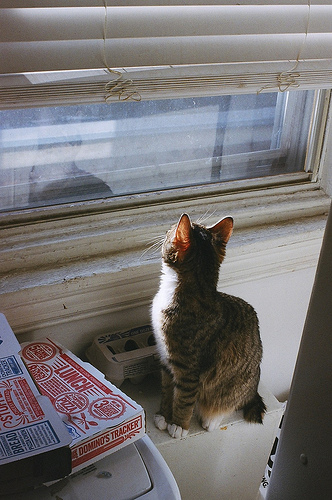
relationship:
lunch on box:
[51, 361, 95, 402] [48, 366, 94, 409]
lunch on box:
[51, 361, 95, 402] [14, 333, 168, 463]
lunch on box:
[51, 361, 95, 402] [22, 334, 158, 486]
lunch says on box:
[51, 361, 95, 402] [22, 334, 158, 486]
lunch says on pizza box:
[51, 361, 95, 402] [36, 341, 133, 441]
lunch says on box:
[51, 361, 95, 402] [23, 334, 158, 476]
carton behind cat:
[85, 320, 158, 388] [149, 213, 267, 438]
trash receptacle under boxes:
[46, 432, 186, 498] [0, 313, 150, 489]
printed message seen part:
[56, 410, 148, 460] [114, 425, 130, 432]